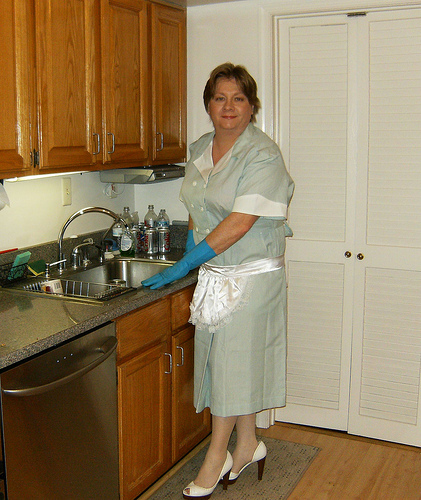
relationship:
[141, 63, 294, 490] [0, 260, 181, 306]
woman standing next to sink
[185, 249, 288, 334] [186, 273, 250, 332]
apron has trim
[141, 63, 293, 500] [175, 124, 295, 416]
woman wearing dress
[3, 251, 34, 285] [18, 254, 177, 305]
sponge beside sink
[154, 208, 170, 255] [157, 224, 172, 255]
bottles and soda cans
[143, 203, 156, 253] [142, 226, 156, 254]
bottles and soda cans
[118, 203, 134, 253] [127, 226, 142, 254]
bottles and soda cans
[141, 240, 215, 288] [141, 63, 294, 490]
glove on a woman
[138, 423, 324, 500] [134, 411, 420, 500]
mat on wood flooring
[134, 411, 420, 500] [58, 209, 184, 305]
wood flooring in front of a sink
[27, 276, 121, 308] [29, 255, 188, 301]
drainer in sink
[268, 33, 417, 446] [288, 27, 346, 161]
doors covered in slats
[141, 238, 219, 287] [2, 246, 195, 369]
glove resting on gray counter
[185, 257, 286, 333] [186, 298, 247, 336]
apron with lace edging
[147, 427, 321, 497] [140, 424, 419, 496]
mat on floor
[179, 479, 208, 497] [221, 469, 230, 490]
dress shoe with heel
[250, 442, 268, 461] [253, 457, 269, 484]
dress shoe with heel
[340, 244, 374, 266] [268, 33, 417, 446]
knobs on doors